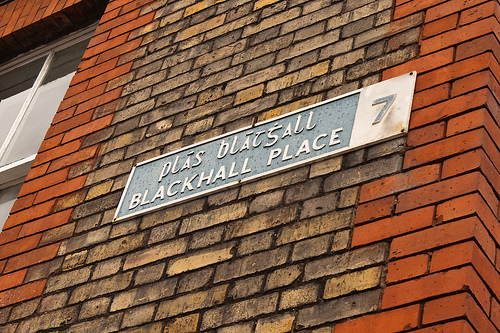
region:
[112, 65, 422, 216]
blue and white sign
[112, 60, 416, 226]
sign on the brick wall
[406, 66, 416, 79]
tiny black bolt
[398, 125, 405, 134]
bolt in the bottom corner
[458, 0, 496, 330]
corner of the building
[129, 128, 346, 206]
white writing in all caps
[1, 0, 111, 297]
window on the side of the building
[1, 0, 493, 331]
building is made of brick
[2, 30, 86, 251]
white lines on the window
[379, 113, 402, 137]
black spot on the sign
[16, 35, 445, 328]
this is an urban setting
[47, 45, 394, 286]
this is outside a buliding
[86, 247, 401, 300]
the building is old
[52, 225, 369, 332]
the building is made of brick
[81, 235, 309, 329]
the brick is yellow and black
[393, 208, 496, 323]
the brick is red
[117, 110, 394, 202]
this is an address sign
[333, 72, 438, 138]
the number is 7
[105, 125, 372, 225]
this says blackhall place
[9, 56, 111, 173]
this is a window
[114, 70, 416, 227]
the street sign is made of metal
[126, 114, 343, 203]
lettering is on the sign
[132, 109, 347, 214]
the lettering is white in color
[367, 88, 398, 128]
a number is on the sign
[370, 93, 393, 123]
the sign is black in color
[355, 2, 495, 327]
the bricks are red in color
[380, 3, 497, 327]
the bricks are at a corner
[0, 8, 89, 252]
a window is on the building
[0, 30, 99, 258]
the window frame is white in color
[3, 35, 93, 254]
the window frame has glass panes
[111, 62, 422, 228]
grey and white sign on side of building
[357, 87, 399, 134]
grey number on grey and white sign on building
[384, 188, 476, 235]
red bricks on side of building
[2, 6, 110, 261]
white framed window on front of building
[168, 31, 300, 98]
orange and tan bricks on front of building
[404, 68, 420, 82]
round black screw on sign on front of building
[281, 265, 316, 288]
crack in brick on front of building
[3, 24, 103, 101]
shadow on top of window on front of building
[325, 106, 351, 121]
grey specks in sign on front of building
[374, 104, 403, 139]
dirt streak on sign on front of building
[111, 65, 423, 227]
sign on the wall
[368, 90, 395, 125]
blue seven on the sign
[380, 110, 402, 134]
black mark on the sign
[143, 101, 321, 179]
writing that is not English